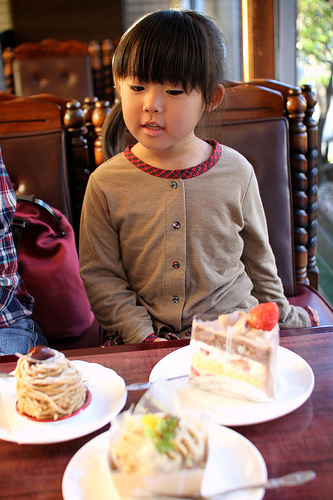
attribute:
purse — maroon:
[10, 192, 103, 328]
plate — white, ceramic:
[53, 412, 278, 498]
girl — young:
[94, 12, 282, 257]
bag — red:
[11, 195, 94, 341]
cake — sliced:
[179, 287, 283, 404]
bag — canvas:
[11, 199, 100, 322]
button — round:
[168, 180, 182, 191]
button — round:
[169, 219, 180, 229]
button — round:
[170, 261, 181, 270]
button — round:
[171, 294, 181, 303]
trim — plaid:
[118, 139, 229, 185]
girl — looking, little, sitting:
[77, 5, 302, 340]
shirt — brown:
[77, 142, 300, 347]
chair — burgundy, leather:
[111, 79, 319, 265]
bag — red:
[13, 188, 110, 343]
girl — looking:
[52, 8, 304, 376]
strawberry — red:
[245, 301, 277, 330]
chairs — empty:
[93, 74, 331, 333]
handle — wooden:
[12, 191, 59, 232]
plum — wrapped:
[25, 346, 55, 366]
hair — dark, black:
[109, 8, 226, 109]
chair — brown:
[1, 97, 93, 255]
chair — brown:
[92, 83, 331, 326]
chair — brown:
[1, 39, 102, 98]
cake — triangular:
[188, 301, 281, 403]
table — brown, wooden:
[0, 324, 331, 498]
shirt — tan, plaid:
[78, 138, 317, 343]